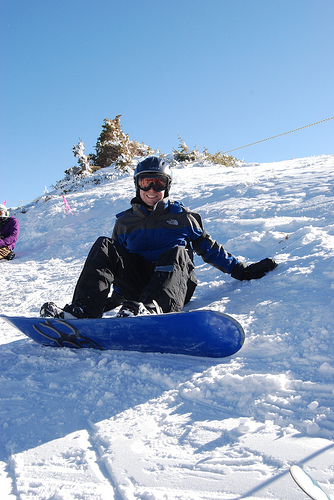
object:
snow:
[254, 217, 291, 237]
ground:
[91, 384, 252, 405]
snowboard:
[0, 310, 248, 361]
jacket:
[110, 196, 236, 276]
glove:
[243, 257, 278, 280]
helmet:
[133, 155, 173, 192]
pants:
[65, 235, 197, 318]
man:
[39, 154, 277, 317]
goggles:
[135, 174, 172, 192]